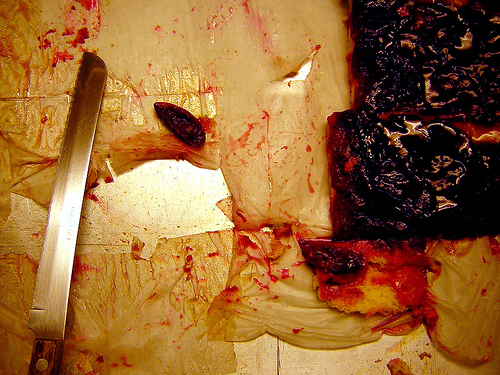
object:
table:
[0, 1, 495, 374]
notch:
[29, 301, 46, 318]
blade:
[25, 46, 112, 338]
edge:
[22, 49, 82, 335]